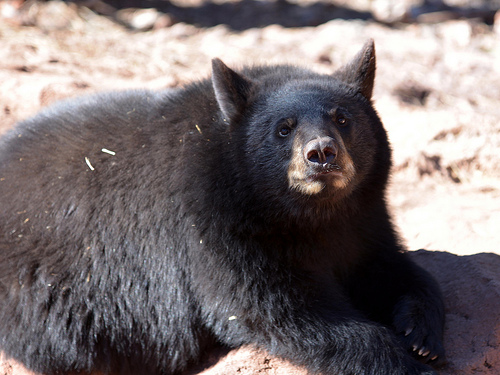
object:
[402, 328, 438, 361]
nails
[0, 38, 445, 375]
bear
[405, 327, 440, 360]
claws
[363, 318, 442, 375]
paw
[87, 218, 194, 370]
fur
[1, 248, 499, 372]
platform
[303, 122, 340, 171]
nose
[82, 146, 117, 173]
debris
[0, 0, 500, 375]
zoo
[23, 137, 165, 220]
fur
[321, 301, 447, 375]
bear's paws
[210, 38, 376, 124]
ears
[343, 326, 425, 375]
paw